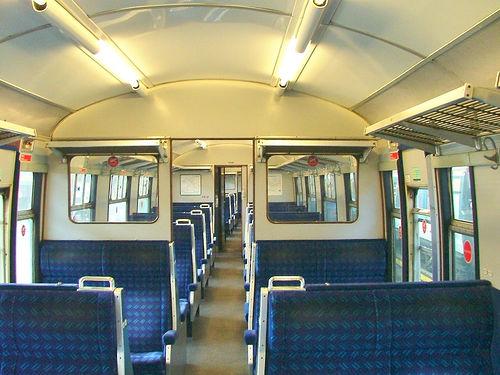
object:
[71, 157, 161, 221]
windshield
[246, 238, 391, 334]
seat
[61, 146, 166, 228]
window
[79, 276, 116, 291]
handle bar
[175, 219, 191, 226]
handle bar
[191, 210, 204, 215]
handle bar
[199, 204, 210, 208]
handle bar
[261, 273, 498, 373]
bench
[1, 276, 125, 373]
bench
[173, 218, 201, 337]
bench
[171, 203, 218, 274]
bench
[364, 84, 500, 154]
rack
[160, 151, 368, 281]
train interior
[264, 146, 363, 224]
window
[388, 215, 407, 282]
window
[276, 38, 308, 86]
light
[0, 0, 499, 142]
ceiling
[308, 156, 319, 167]
sticker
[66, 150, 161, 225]
window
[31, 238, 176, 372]
bench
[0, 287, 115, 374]
blue fabric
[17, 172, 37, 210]
window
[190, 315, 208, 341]
shadow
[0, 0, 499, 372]
passenger wagon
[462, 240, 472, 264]
red sticker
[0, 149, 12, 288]
exit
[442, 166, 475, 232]
window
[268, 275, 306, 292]
handle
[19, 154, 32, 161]
sticker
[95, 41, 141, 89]
light